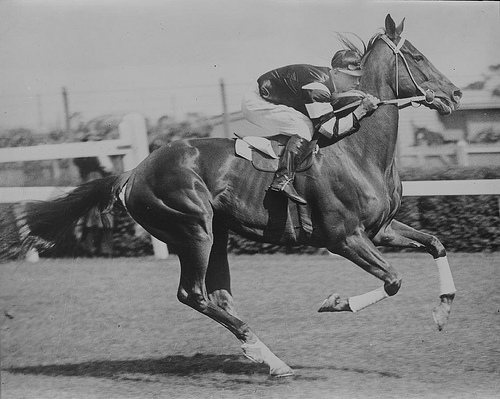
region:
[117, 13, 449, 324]
brown horse with rider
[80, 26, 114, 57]
white clouds in blue sky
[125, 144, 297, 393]
Powerful back legs of a horse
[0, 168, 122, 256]
Long hair of a horse's tail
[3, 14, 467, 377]
A horse being ridden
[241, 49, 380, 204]
A small man riding a horse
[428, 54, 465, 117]
Snout of a horse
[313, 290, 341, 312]
Front hoof of a horse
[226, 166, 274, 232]
Visible rib cage on a running horse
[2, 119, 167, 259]
White fence of an enclosure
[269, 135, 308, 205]
Leather boot of a jockey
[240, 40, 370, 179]
man is riding horse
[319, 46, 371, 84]
man has dark cap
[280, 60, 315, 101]
man has dark shirt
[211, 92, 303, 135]
man has white pants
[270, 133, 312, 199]
man has dark boots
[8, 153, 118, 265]
horse has long tail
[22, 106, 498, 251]
white fence behind horse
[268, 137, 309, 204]
a black boot of a jockey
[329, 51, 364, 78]
a hat on a jockey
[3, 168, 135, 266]
a tail of a horse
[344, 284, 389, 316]
taped ankles on a horse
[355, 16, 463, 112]
a bridle on a horse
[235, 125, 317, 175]
a saddle on a horse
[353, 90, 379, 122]
a hand holding the reins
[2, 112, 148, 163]
a white railing by a track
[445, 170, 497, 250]
a line of scrubs behind the fence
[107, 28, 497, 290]
horse with rider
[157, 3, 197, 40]
white clouds in blue sky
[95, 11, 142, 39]
white clouds in blue sky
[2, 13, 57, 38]
white clouds in blue sky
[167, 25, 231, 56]
white clouds in blue sky